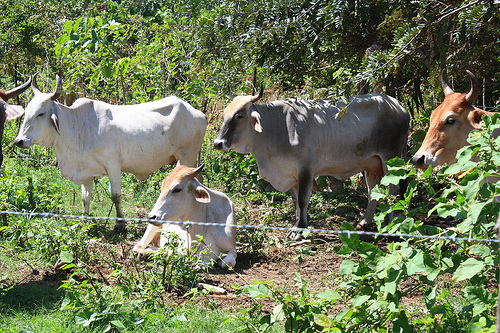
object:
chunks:
[51, 74, 63, 101]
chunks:
[30, 73, 41, 93]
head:
[214, 83, 263, 153]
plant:
[0, 0, 500, 105]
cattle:
[132, 159, 236, 268]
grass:
[0, 164, 500, 333]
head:
[15, 73, 62, 149]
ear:
[467, 108, 488, 129]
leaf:
[338, 162, 500, 333]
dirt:
[179, 191, 384, 311]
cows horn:
[442, 68, 479, 102]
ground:
[3, 134, 500, 329]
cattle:
[214, 81, 410, 240]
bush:
[223, 112, 500, 333]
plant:
[0, 114, 500, 333]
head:
[411, 69, 489, 169]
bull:
[412, 70, 499, 189]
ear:
[196, 186, 211, 203]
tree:
[212, 0, 500, 115]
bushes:
[215, 113, 500, 333]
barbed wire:
[0, 211, 499, 243]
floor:
[0, 152, 500, 333]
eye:
[172, 188, 182, 193]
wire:
[0, 211, 500, 243]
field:
[7, 3, 498, 330]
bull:
[14, 72, 208, 234]